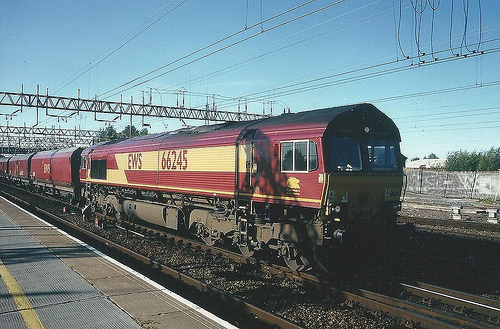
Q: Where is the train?
A: On the track.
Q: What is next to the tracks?
A: Platform.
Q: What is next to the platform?
A: Train.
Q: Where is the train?
A: On train.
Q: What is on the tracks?
A: Train.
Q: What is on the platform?
A: Painted line.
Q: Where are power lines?
A: Above train.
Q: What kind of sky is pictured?
A: Clear.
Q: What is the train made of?
A: Metal.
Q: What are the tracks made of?
A: Iron.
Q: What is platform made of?
A: Concrete.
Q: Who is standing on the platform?
A: Not one person.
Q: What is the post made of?
A: Metal.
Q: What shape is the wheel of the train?
A: Round.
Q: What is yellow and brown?
A: Train.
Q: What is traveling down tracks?
A: Train.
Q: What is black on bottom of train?
A: Wheels.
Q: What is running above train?
A: Wires.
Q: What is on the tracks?
A: A train?.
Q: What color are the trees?
A: Green.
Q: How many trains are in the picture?
A: One.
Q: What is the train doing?
A: Sitting.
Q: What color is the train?
A: Burgundy and yellow.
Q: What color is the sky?
A: Blue.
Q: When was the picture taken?
A: During the day.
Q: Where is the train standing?
A: On train tracks.